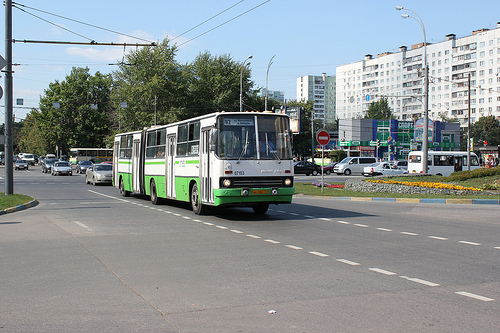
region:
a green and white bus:
[100, 95, 298, 222]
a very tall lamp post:
[380, 3, 442, 190]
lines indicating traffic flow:
[237, 226, 466, 303]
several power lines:
[7, 6, 279, 71]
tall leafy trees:
[47, 67, 211, 109]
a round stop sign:
[301, 125, 350, 161]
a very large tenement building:
[337, 39, 499, 109]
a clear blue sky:
[217, 8, 344, 51]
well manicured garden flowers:
[346, 175, 493, 202]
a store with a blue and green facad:
[342, 120, 459, 157]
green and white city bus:
[108, 105, 308, 213]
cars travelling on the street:
[15, 132, 118, 185]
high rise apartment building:
[329, 30, 495, 146]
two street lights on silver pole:
[384, 0, 441, 195]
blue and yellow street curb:
[310, 185, 498, 217]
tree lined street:
[11, 36, 348, 218]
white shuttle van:
[398, 144, 486, 184]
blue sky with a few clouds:
[18, 3, 498, 87]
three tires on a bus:
[112, 175, 209, 217]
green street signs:
[332, 134, 464, 161]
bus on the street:
[108, 109, 300, 226]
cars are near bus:
[42, 155, 111, 183]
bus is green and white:
[112, 111, 295, 211]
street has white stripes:
[88, 186, 499, 306]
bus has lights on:
[207, 115, 297, 203]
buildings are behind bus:
[296, 26, 499, 141]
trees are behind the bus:
[100, 48, 257, 127]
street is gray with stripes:
[37, 178, 499, 313]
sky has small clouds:
[15, 3, 323, 85]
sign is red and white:
[316, 126, 330, 183]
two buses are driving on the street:
[68, 109, 295, 216]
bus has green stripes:
[118, 158, 199, 164]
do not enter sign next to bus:
[315, 130, 329, 145]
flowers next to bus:
[310, 177, 485, 195]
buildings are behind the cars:
[248, 20, 498, 160]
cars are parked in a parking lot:
[294, 150, 482, 175]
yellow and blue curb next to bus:
[293, 192, 498, 205]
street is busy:
[0, 161, 499, 331]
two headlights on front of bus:
[223, 177, 292, 185]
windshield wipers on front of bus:
[236, 137, 283, 164]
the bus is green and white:
[95, 107, 307, 232]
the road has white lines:
[71, 150, 498, 321]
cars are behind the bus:
[13, 98, 320, 230]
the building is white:
[291, 22, 498, 158]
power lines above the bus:
[7, 2, 329, 240]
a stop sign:
[310, 121, 346, 194]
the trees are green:
[30, 31, 287, 186]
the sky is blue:
[4, 2, 498, 51]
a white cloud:
[67, 22, 206, 83]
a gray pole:
[0, 0, 33, 202]